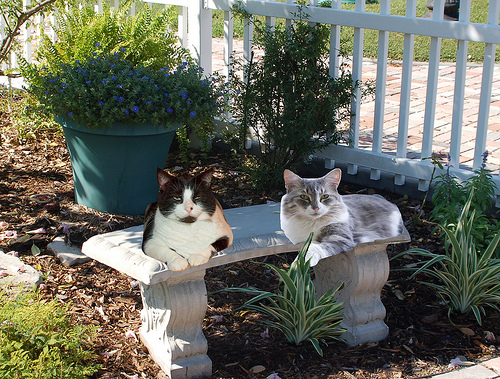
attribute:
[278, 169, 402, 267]
cat — photoshopped, grey, white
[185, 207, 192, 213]
nose — pink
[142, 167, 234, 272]
cat — black, white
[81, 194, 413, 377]
bench — stone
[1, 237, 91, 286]
stones — grey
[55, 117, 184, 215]
flower pot — green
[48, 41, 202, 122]
flowers — blue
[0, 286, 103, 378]
leaves — green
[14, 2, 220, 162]
plant — green, large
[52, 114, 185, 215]
pot — green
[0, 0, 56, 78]
branch — wooden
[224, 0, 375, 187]
tree — green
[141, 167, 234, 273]
fur — black, white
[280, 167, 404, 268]
fur — gray, white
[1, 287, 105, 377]
bush — green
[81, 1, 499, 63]
grass — green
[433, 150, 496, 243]
shrub — green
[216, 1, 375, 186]
plant — dark green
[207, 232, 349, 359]
foliage — green, white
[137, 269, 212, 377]
leg — carved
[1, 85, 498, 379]
dirt — brown